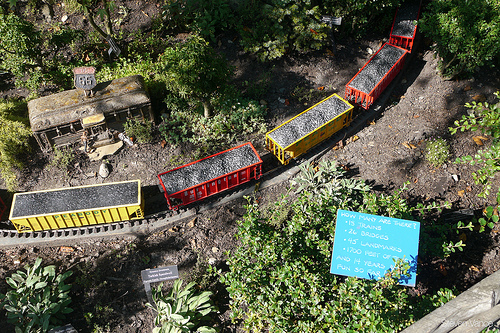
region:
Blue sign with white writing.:
[325, 200, 421, 286]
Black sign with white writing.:
[135, 260, 180, 280]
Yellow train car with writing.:
[5, 175, 145, 225]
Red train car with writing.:
[155, 135, 270, 205]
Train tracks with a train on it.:
[0, 0, 427, 250]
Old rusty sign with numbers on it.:
[67, 62, 93, 92]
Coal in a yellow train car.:
[10, 181, 132, 217]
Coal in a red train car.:
[156, 140, 261, 195]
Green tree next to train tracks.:
[155, 46, 266, 207]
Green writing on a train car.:
[283, 108, 350, 160]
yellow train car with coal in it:
[10, 176, 150, 241]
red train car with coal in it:
[143, 136, 282, 207]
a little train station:
[7, 65, 169, 170]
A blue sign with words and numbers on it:
[318, 192, 435, 291]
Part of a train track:
[7, 219, 149, 237]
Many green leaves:
[203, 243, 324, 322]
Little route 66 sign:
[68, 61, 97, 96]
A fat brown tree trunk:
[189, 88, 219, 123]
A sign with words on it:
[133, 253, 189, 318]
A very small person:
[75, 128, 97, 160]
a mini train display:
[13, 13, 458, 323]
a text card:
[336, 205, 435, 297]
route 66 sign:
[62, 60, 116, 97]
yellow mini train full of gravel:
[11, 182, 180, 237]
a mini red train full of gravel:
[138, 139, 285, 220]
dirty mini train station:
[23, 86, 180, 161]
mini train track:
[1, 157, 356, 259]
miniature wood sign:
[131, 256, 219, 309]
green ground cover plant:
[116, 48, 283, 140]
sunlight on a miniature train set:
[249, 72, 479, 165]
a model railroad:
[0, 2, 451, 249]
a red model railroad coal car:
[150, 138, 268, 214]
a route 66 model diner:
[25, 61, 161, 171]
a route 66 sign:
[66, 56, 96, 98]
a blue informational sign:
[325, 201, 420, 291]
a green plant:
[0, 255, 75, 325]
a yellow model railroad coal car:
[5, 170, 145, 235]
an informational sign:
[134, 263, 184, 303]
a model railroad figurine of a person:
[73, 129, 96, 156]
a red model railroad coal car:
[342, 39, 414, 114]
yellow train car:
[260, 74, 361, 176]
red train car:
[156, 132, 264, 215]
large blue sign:
[314, 209, 430, 302]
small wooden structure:
[24, 61, 174, 176]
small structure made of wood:
[136, 239, 191, 301]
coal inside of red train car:
[159, 145, 251, 200]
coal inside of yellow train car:
[271, 93, 350, 147]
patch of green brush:
[424, 79, 499, 196]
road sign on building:
[66, 57, 105, 101]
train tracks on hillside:
[6, 5, 423, 257]